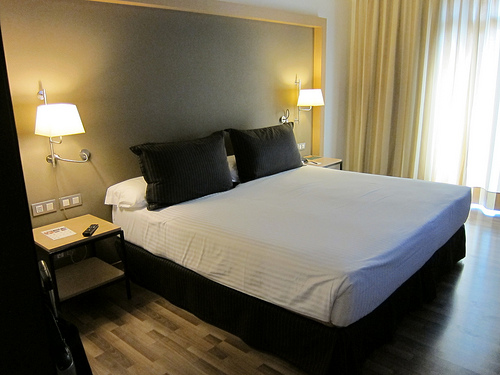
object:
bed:
[100, 155, 473, 364]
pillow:
[130, 131, 237, 211]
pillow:
[229, 122, 304, 183]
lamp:
[36, 99, 89, 169]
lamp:
[298, 89, 324, 112]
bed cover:
[103, 166, 470, 326]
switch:
[72, 195, 80, 206]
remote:
[82, 223, 98, 236]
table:
[33, 214, 132, 316]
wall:
[0, 0, 328, 227]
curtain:
[341, 0, 500, 211]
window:
[415, 0, 499, 185]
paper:
[42, 227, 76, 240]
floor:
[61, 206, 500, 374]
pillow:
[105, 177, 148, 211]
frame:
[108, 0, 328, 29]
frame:
[314, 20, 326, 158]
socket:
[46, 203, 55, 210]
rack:
[54, 258, 125, 299]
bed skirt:
[121, 225, 359, 334]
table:
[306, 155, 343, 170]